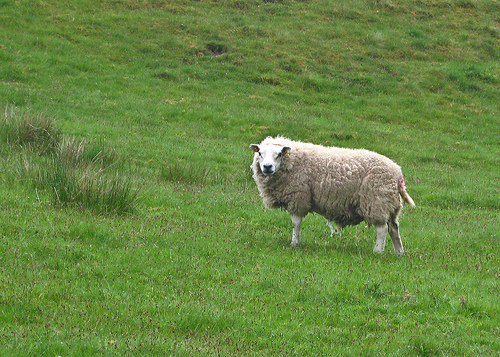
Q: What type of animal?
A: Sheep.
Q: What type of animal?
A: Sheep.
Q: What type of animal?
A: Sheep.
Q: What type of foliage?
A: Grass.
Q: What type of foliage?
A: Grass.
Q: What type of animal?
A: Sheep.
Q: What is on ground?
A: Grass.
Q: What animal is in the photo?
A: A sheep.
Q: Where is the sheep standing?
A: In a field.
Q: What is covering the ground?
A: Grass.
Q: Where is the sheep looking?
A: At the camera.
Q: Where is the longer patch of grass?
A: In front of the sheep.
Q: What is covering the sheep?
A: Wool.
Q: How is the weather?
A: Sunny.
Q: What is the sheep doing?
A: Standing in grass.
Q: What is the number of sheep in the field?
A: One.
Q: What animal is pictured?
A: A sheep.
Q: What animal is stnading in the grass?
A: A sheep.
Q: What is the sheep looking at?
A: The camera.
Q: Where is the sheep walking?
A: In an open field.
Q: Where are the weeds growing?
A: In the open field.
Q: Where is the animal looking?
A: At the camera.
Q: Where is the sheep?
A: In the middle of the field.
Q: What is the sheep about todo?
A: Feed on grass.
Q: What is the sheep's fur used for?
A: Clothing.